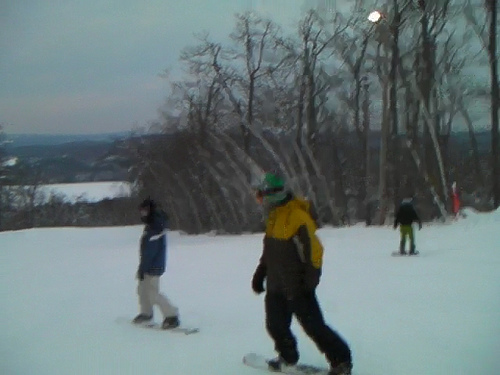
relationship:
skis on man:
[122, 309, 197, 336] [134, 195, 174, 327]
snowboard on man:
[236, 348, 375, 373] [259, 181, 343, 372]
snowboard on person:
[390, 250, 421, 257] [393, 199, 422, 253]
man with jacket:
[259, 181, 343, 372] [260, 203, 328, 293]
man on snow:
[259, 181, 343, 372] [3, 202, 495, 373]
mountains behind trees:
[2, 118, 499, 175] [2, 0, 499, 226]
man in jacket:
[134, 192, 174, 327] [135, 214, 166, 275]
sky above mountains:
[6, 0, 495, 136] [2, 118, 499, 175]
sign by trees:
[449, 184, 465, 215] [2, 0, 499, 226]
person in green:
[393, 199, 422, 253] [402, 227, 416, 256]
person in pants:
[393, 199, 422, 253] [400, 226, 420, 253]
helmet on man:
[256, 173, 291, 208] [259, 181, 343, 372]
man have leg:
[259, 181, 343, 372] [125, 275, 359, 374]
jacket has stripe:
[135, 214, 166, 275] [140, 225, 171, 244]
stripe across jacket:
[139, 232, 175, 242] [135, 214, 166, 275]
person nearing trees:
[393, 199, 422, 253] [2, 0, 499, 226]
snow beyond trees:
[7, 169, 145, 202] [2, 0, 499, 226]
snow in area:
[7, 169, 145, 202] [1, 175, 135, 211]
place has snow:
[3, 1, 496, 367] [3, 202, 495, 373]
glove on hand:
[253, 266, 274, 295] [251, 265, 269, 294]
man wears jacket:
[134, 192, 174, 327] [135, 214, 166, 275]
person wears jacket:
[393, 199, 422, 253] [392, 206, 421, 231]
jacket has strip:
[135, 214, 166, 275] [146, 229, 168, 249]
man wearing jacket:
[259, 181, 343, 372] [260, 203, 328, 293]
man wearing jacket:
[134, 195, 174, 327] [135, 214, 166, 275]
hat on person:
[395, 195, 418, 207] [393, 199, 422, 253]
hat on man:
[138, 198, 157, 218] [134, 195, 174, 327]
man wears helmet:
[259, 181, 343, 372] [256, 173, 291, 208]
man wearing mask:
[134, 192, 174, 327] [140, 201, 154, 224]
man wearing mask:
[259, 181, 343, 372] [258, 182, 286, 204]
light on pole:
[358, 11, 391, 24] [372, 18, 398, 233]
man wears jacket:
[259, 181, 343, 372] [260, 203, 328, 293]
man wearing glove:
[259, 181, 343, 372] [253, 266, 274, 295]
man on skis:
[134, 192, 174, 327] [122, 317, 198, 336]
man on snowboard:
[259, 181, 343, 372] [236, 348, 375, 373]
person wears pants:
[393, 199, 422, 253] [400, 226, 420, 253]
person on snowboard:
[393, 199, 422, 253] [390, 250, 421, 257]